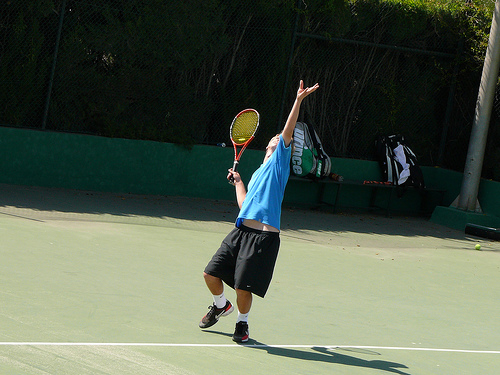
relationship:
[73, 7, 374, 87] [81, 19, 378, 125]
trees behind fence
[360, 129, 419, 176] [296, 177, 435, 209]
backpack on bench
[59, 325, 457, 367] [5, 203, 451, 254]
lines on ground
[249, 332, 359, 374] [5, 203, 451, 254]
shadow on ground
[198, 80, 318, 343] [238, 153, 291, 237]
player wearing shirt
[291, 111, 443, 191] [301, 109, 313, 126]
bags holds equipment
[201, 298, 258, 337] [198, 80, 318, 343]
tennis shoes on player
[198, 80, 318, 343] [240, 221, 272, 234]
player has midriff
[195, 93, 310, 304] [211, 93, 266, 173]
player holding racket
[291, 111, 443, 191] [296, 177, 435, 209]
bags on bench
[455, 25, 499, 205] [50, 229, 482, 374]
pole on court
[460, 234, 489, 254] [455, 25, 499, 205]
ball near pole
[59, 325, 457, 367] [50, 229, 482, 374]
lines on court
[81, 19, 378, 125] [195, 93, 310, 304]
fence behind player